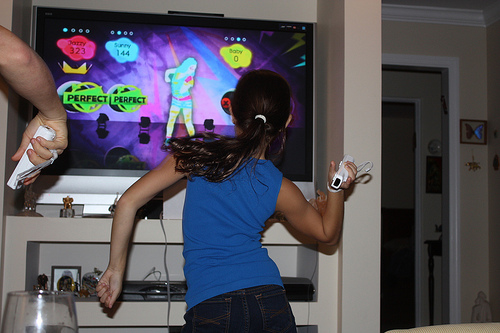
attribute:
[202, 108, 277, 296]
girl — young 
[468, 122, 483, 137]
butterfly — blue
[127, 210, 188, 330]
wire — gray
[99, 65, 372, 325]
person — enjoying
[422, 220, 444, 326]
console table — small 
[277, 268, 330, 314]
console — video game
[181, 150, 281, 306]
shirt — blue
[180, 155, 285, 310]
sleeveless shirt — blue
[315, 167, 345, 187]
ground — blue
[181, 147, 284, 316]
t-shirt — blue 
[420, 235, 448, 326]
table — small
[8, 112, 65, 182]
hand — large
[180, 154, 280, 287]
shirt — blue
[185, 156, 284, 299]
shirt — sleeveless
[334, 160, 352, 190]
controller — game